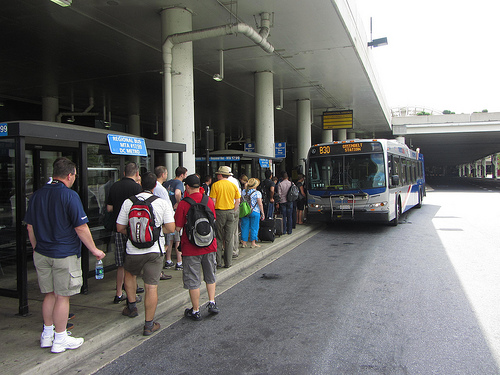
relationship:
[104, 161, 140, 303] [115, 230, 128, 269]
man wearing shorts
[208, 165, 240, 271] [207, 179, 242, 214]
man wearing shirt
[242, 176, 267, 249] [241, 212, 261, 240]
woman wearing pants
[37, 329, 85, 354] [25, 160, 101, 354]
shoes on man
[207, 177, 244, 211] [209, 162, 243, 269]
shirt on man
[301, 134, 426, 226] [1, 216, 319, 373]
bus near curb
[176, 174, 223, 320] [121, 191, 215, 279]
man in shirt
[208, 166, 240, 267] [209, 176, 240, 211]
man wearing shirt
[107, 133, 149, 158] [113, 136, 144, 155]
sign with letters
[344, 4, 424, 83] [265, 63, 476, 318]
light above bus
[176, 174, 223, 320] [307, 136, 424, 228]
man waiting for bus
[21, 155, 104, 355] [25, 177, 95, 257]
man has shirt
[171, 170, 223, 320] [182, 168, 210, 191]
man wearing hat